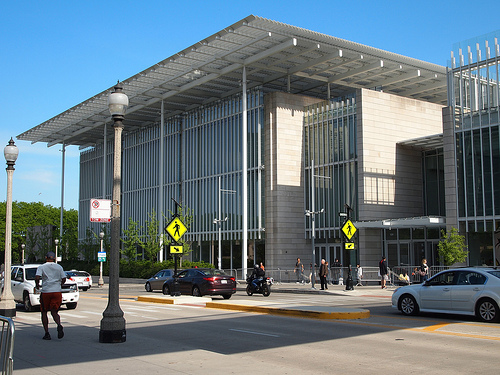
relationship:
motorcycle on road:
[240, 264, 282, 299] [57, 256, 489, 374]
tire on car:
[392, 293, 420, 321] [378, 264, 498, 324]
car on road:
[141, 264, 187, 297] [57, 256, 489, 374]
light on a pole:
[99, 86, 137, 127] [89, 117, 138, 353]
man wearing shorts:
[34, 248, 75, 342] [30, 286, 70, 310]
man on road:
[34, 248, 75, 342] [0, 283, 500, 374]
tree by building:
[431, 225, 472, 275] [6, 13, 499, 291]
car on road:
[155, 260, 239, 305] [57, 256, 489, 374]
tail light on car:
[204, 274, 239, 291] [141, 264, 187, 297]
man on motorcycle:
[244, 258, 270, 284] [240, 264, 282, 299]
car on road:
[378, 264, 498, 324] [57, 256, 489, 374]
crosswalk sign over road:
[157, 211, 195, 259] [57, 256, 489, 374]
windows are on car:
[419, 270, 493, 292] [378, 264, 498, 324]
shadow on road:
[3, 297, 446, 362] [57, 256, 489, 374]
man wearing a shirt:
[34, 248, 75, 342] [31, 261, 78, 299]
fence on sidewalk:
[205, 256, 499, 295] [127, 266, 500, 305]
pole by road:
[89, 117, 138, 353] [57, 256, 489, 374]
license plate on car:
[218, 273, 231, 287] [155, 260, 239, 305]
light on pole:
[99, 86, 137, 127] [89, 117, 138, 353]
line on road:
[119, 302, 315, 356] [57, 256, 489, 374]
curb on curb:
[198, 281, 370, 328] [206, 300, 370, 320]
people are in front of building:
[279, 246, 442, 290] [6, 13, 499, 291]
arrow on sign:
[345, 239, 357, 253] [336, 242, 368, 252]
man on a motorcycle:
[244, 258, 270, 284] [240, 264, 282, 299]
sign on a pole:
[83, 193, 114, 227] [97, 124, 115, 290]